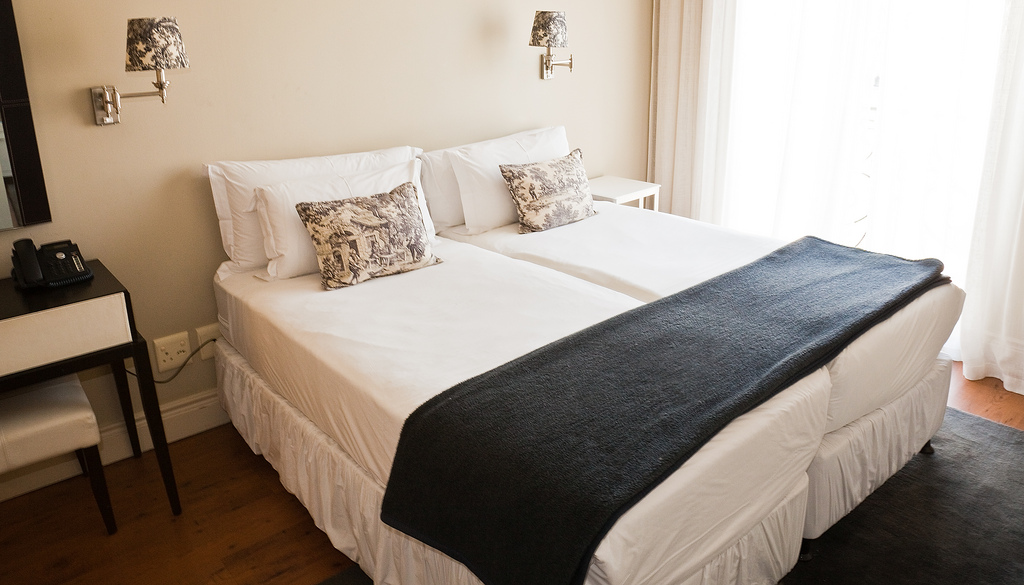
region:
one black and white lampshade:
[113, 9, 187, 77]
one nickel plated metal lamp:
[81, 14, 193, 125]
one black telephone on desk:
[9, 229, 98, 306]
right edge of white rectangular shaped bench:
[0, 375, 124, 543]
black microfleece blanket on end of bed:
[378, 226, 958, 580]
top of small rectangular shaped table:
[584, 163, 662, 214]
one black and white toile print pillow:
[291, 179, 447, 294]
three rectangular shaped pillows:
[193, 141, 444, 298]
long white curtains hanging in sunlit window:
[645, 2, 760, 234]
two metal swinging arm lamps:
[60, 2, 580, 127]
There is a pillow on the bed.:
[299, 177, 437, 291]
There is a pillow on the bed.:
[512, 147, 592, 220]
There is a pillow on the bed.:
[447, 125, 572, 234]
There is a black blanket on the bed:
[378, 235, 939, 578]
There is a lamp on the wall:
[83, 14, 185, 126]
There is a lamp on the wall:
[522, 5, 574, 83]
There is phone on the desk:
[8, 236, 88, 301]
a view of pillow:
[223, 75, 432, 272]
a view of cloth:
[438, 356, 673, 557]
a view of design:
[315, 171, 426, 248]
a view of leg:
[62, 369, 212, 507]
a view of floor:
[211, 474, 289, 545]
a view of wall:
[271, 62, 396, 121]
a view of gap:
[765, 383, 865, 542]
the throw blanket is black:
[370, 222, 953, 576]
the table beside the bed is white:
[582, 157, 672, 215]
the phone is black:
[4, 226, 99, 296]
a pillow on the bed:
[239, 124, 455, 320]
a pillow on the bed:
[228, 154, 412, 314]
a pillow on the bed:
[257, 151, 397, 335]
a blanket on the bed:
[485, 259, 719, 487]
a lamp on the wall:
[512, 10, 567, 109]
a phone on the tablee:
[17, 215, 154, 361]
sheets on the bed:
[248, 195, 622, 534]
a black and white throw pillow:
[295, 177, 436, 288]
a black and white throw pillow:
[494, 150, 596, 233]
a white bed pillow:
[245, 157, 438, 281]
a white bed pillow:
[206, 143, 422, 267]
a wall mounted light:
[89, 14, 187, 131]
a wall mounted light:
[531, 10, 576, 77]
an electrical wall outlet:
[155, 327, 193, 370]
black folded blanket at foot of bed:
[386, 216, 940, 583]